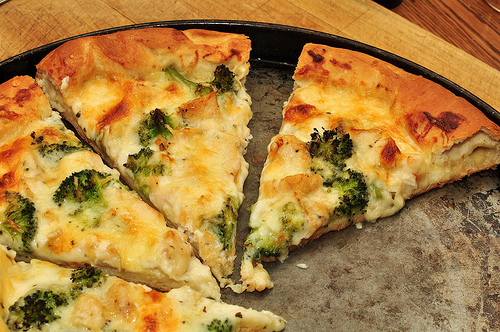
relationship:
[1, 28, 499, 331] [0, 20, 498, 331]
pizza in tray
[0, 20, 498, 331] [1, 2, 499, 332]
tray on table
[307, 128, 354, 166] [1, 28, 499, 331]
broccoli on pizza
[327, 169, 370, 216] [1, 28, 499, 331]
broccoli on pizza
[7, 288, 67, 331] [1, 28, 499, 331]
broccoli on pizza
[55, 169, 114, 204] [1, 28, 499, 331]
broccoli on pizza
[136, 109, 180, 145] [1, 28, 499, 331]
broccoli on pizza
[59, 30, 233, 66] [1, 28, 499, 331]
crust on pizza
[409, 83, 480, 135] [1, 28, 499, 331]
crust on pizza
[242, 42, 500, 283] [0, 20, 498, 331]
slice on tray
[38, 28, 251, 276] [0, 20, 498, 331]
slice on tray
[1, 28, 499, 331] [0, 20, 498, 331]
pizza on tray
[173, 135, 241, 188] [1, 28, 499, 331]
cheese on pizza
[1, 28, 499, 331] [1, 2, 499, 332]
pizza on table